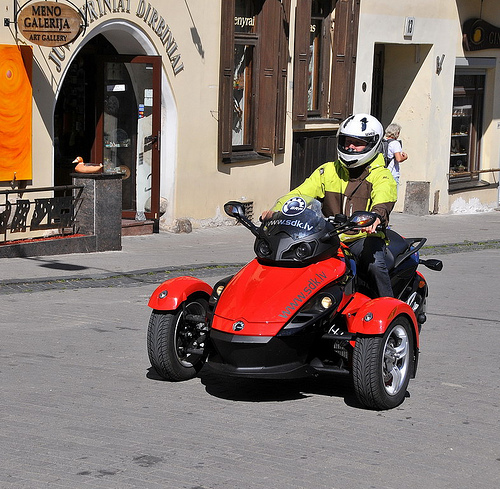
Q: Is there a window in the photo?
A: Yes, there is a window.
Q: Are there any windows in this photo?
A: Yes, there is a window.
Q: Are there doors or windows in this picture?
A: Yes, there is a window.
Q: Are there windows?
A: Yes, there is a window.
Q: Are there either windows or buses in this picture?
A: Yes, there is a window.